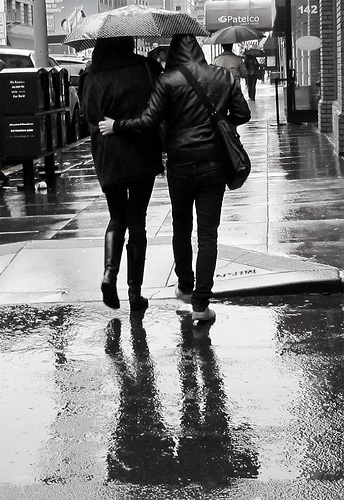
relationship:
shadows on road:
[177, 314, 258, 486] [4, 305, 342, 499]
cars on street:
[0, 47, 91, 143] [197, 37, 239, 66]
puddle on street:
[2, 311, 69, 412] [0, 291, 342, 449]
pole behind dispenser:
[31, 0, 48, 70] [0, 66, 66, 197]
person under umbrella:
[70, 37, 173, 316] [60, 3, 211, 41]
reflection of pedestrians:
[103, 307, 258, 498] [81, 34, 249, 322]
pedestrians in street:
[81, 34, 249, 322] [0, 289, 343, 498]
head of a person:
[89, 35, 135, 66] [76, 35, 165, 309]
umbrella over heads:
[56, 5, 222, 58] [76, 24, 222, 74]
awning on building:
[200, 1, 279, 36] [276, 0, 342, 130]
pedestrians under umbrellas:
[98, 29, 252, 323] [73, 5, 281, 47]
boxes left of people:
[0, 67, 70, 159] [75, 36, 261, 294]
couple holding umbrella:
[41, 37, 263, 342] [51, 11, 209, 42]